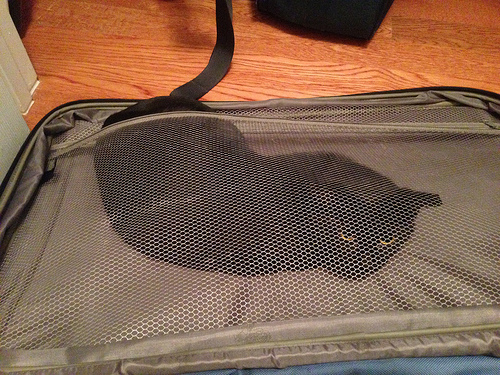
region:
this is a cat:
[94, 94, 452, 295]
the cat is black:
[104, 100, 394, 290]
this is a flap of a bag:
[51, 216, 183, 328]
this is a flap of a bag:
[74, 176, 151, 258]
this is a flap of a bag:
[234, 238, 318, 316]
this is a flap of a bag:
[370, 242, 442, 321]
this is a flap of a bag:
[386, 158, 477, 271]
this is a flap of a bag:
[141, 245, 243, 340]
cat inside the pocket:
[60, 74, 437, 304]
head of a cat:
[316, 172, 441, 287]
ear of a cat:
[303, 164, 353, 228]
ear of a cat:
[398, 181, 451, 232]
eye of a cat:
[339, 217, 371, 247]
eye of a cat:
[371, 227, 410, 252]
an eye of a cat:
[337, 225, 359, 238]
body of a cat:
[85, 74, 352, 293]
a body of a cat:
[83, 56, 380, 291]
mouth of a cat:
[332, 253, 384, 293]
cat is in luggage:
[79, 98, 394, 267]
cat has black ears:
[316, 172, 446, 194]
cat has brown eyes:
[318, 232, 417, 256]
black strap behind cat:
[162, 0, 252, 96]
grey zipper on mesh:
[49, 112, 481, 157]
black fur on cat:
[97, 103, 299, 190]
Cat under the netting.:
[75, 0, 449, 292]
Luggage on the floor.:
[0, 88, 497, 374]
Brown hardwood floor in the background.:
[20, 1, 498, 134]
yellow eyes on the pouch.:
[325, 218, 400, 253]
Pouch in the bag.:
[15, 108, 495, 359]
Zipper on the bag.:
[467, 104, 498, 136]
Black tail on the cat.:
[167, 0, 242, 101]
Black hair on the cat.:
[94, 1, 447, 283]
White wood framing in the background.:
[1, 0, 44, 123]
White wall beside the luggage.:
[0, 78, 30, 192]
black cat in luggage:
[101, 87, 428, 295]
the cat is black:
[96, 95, 441, 276]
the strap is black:
[168, 0, 233, 101]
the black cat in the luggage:
[0, 96, 499, 371]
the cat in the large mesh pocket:
[1, 93, 499, 374]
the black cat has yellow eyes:
[91, 95, 441, 281]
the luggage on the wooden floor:
[1, 0, 499, 372]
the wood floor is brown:
[9, 0, 498, 130]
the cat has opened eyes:
[93, 94, 440, 281]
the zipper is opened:
[1, 86, 496, 373]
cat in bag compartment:
[94, 80, 439, 289]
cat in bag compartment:
[86, 82, 438, 291]